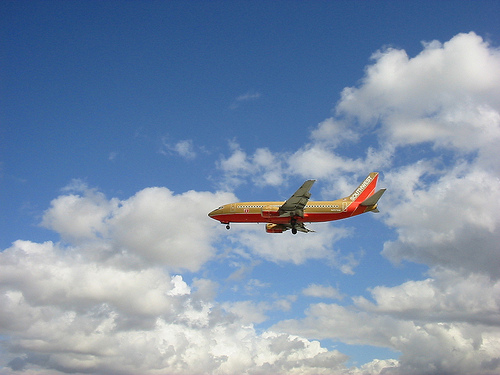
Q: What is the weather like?
A: It is cloudy.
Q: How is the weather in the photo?
A: It is cloudy.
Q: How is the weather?
A: It is cloudy.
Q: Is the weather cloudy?
A: Yes, it is cloudy.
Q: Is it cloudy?
A: Yes, it is cloudy.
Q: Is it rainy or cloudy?
A: It is cloudy.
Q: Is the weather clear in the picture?
A: No, it is cloudy.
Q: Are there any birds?
A: No, there are no birds.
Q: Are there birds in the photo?
A: No, there are no birds.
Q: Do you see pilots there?
A: No, there are no pilots.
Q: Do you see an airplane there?
A: Yes, there is an airplane.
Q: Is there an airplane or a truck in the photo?
A: Yes, there is an airplane.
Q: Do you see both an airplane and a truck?
A: No, there is an airplane but no trucks.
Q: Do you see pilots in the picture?
A: No, there are no pilots.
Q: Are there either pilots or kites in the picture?
A: No, there are no pilots or kites.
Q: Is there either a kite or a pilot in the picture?
A: No, there are no pilots or kites.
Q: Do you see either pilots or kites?
A: No, there are no pilots or kites.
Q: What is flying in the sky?
A: The plane is flying in the sky.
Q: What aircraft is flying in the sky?
A: The aircraft is an airplane.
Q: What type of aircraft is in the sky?
A: The aircraft is an airplane.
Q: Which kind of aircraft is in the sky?
A: The aircraft is an airplane.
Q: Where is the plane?
A: The plane is in the sky.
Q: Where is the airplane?
A: The plane is in the sky.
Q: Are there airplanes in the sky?
A: Yes, there is an airplane in the sky.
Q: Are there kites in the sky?
A: No, there is an airplane in the sky.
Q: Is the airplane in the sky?
A: Yes, the airplane is in the sky.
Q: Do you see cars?
A: No, there are no cars.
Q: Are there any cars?
A: No, there are no cars.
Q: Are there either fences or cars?
A: No, there are no cars or fences.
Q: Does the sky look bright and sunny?
A: No, the sky is bright but cloudy.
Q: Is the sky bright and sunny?
A: No, the sky is bright but cloudy.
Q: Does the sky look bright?
A: Yes, the sky is bright.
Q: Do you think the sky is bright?
A: Yes, the sky is bright.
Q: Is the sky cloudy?
A: Yes, the sky is cloudy.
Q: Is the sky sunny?
A: No, the sky is cloudy.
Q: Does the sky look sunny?
A: No, the sky is cloudy.